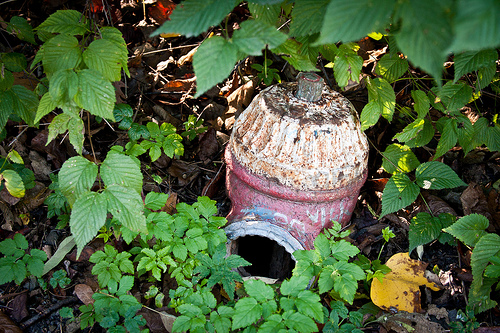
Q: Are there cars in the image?
A: No, there are no cars.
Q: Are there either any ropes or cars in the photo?
A: No, there are no cars or ropes.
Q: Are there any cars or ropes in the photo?
A: No, there are no cars or ropes.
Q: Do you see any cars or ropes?
A: No, there are no cars or ropes.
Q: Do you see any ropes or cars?
A: No, there are no cars or ropes.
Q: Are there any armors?
A: No, there are no armors.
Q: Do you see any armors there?
A: No, there are no armors.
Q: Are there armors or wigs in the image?
A: No, there are no armors or wigs.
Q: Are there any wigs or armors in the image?
A: No, there are no armors or wigs.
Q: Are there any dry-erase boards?
A: No, there are no dry-erase boards.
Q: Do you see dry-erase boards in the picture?
A: No, there are no dry-erase boards.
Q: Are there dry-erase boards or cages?
A: No, there are no dry-erase boards or cages.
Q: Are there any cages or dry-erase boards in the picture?
A: No, there are no dry-erase boards or cages.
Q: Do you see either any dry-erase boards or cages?
A: No, there are no dry-erase boards or cages.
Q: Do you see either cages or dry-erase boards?
A: No, there are no dry-erase boards or cages.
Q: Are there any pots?
A: No, there are no pots.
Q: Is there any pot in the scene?
A: No, there are no pots.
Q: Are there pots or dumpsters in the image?
A: No, there are no pots or dumpsters.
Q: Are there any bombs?
A: No, there are no bombs.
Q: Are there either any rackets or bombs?
A: No, there are no bombs or rackets.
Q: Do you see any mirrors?
A: No, there are no mirrors.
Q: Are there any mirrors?
A: No, there are no mirrors.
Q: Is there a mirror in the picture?
A: No, there are no mirrors.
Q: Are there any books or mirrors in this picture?
A: No, there are no mirrors or books.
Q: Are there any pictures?
A: No, there are no pictures.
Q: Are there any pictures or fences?
A: No, there are no pictures or fences.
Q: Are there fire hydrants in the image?
A: Yes, there is a fire hydrant.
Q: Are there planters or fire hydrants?
A: Yes, there is a fire hydrant.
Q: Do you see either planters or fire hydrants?
A: Yes, there is a fire hydrant.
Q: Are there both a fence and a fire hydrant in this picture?
A: No, there is a fire hydrant but no fences.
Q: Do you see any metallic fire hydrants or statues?
A: Yes, there is a metal fire hydrant.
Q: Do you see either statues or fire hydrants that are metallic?
A: Yes, the fire hydrant is metallic.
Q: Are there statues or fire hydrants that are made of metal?
A: Yes, the fire hydrant is made of metal.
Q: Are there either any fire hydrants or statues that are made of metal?
A: Yes, the fire hydrant is made of metal.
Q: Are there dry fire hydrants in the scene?
A: Yes, there is a dry fire hydrant.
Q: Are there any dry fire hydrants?
A: Yes, there is a dry fire hydrant.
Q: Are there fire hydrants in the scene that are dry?
A: Yes, there is a dry fire hydrant.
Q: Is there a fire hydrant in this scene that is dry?
A: Yes, there is a fire hydrant that is dry.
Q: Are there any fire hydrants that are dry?
A: Yes, there is a fire hydrant that is dry.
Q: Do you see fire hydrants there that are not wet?
A: Yes, there is a dry fire hydrant.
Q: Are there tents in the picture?
A: No, there are no tents.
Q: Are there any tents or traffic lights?
A: No, there are no tents or traffic lights.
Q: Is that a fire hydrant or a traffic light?
A: That is a fire hydrant.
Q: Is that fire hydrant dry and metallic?
A: Yes, the fire hydrant is dry and metallic.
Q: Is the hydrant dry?
A: Yes, the hydrant is dry.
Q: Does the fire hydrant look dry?
A: Yes, the fire hydrant is dry.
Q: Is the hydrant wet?
A: No, the hydrant is dry.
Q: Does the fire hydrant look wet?
A: No, the fire hydrant is dry.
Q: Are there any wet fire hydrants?
A: No, there is a fire hydrant but it is dry.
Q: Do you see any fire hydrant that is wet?
A: No, there is a fire hydrant but it is dry.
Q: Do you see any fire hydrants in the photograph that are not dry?
A: No, there is a fire hydrant but it is dry.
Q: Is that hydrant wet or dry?
A: The hydrant is dry.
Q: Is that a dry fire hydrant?
A: Yes, that is a dry fire hydrant.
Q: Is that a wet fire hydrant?
A: No, that is a dry fire hydrant.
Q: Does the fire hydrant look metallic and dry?
A: Yes, the fire hydrant is metallic and dry.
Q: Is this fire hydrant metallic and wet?
A: No, the fire hydrant is metallic but dry.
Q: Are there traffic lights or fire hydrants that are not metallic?
A: No, there is a fire hydrant but it is metallic.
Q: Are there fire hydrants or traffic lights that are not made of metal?
A: No, there is a fire hydrant but it is made of metal.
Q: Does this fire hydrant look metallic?
A: Yes, the fire hydrant is metallic.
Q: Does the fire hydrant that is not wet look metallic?
A: Yes, the fire hydrant is metallic.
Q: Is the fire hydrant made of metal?
A: Yes, the fire hydrant is made of metal.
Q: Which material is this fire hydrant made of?
A: The fire hydrant is made of metal.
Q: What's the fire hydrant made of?
A: The fire hydrant is made of metal.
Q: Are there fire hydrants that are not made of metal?
A: No, there is a fire hydrant but it is made of metal.